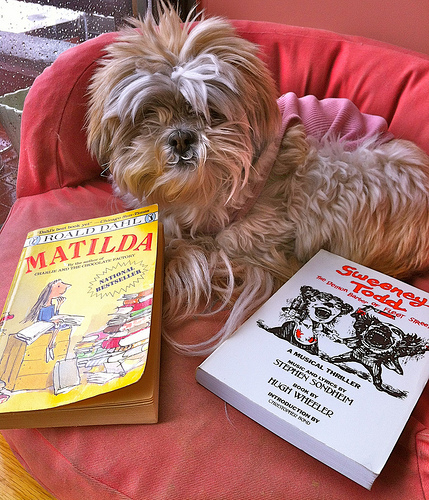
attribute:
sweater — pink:
[176, 90, 397, 240]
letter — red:
[26, 248, 49, 273]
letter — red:
[46, 242, 68, 266]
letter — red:
[67, 241, 88, 258]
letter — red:
[81, 234, 100, 259]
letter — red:
[97, 237, 117, 254]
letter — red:
[87, 236, 96, 254]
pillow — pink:
[1, 169, 422, 496]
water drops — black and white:
[3, 4, 58, 49]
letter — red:
[50, 246, 64, 264]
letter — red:
[21, 251, 48, 271]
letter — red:
[85, 236, 99, 261]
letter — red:
[118, 231, 138, 254]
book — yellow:
[194, 246, 420, 492]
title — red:
[188, 245, 426, 490]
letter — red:
[336, 260, 356, 275]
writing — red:
[338, 261, 426, 316]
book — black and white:
[191, 235, 427, 481]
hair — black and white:
[110, 5, 228, 61]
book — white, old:
[3, 205, 163, 442]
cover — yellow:
[3, 200, 167, 431]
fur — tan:
[217, 147, 400, 232]